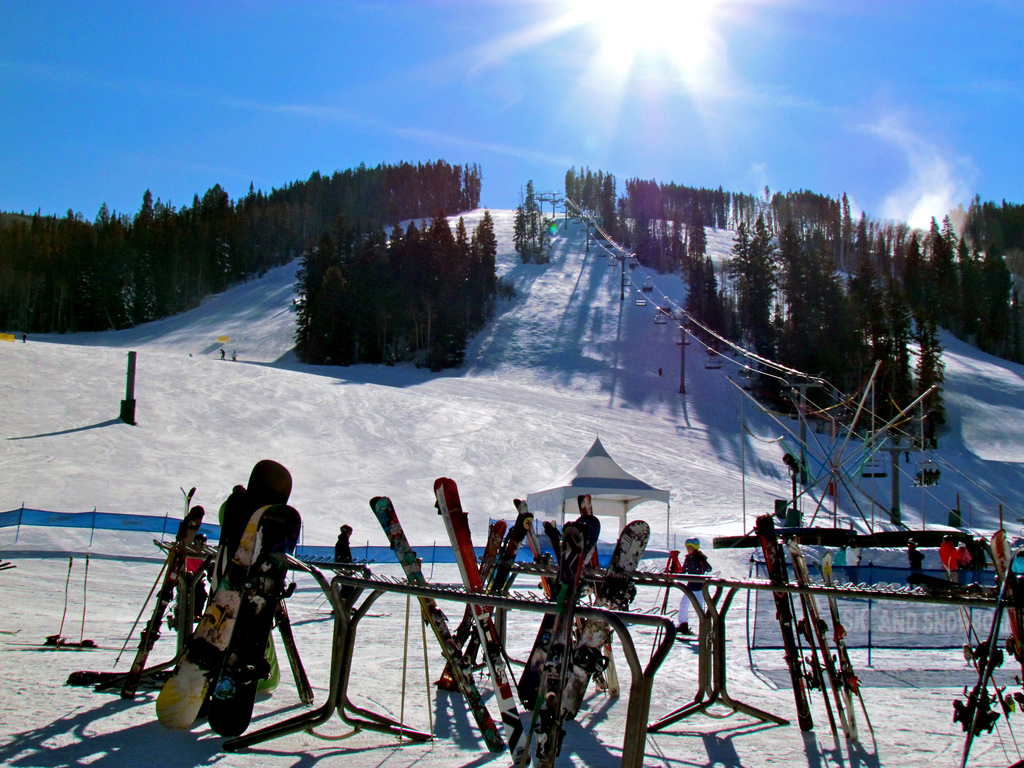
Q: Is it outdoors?
A: Yes, it is outdoors.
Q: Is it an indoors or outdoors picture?
A: It is outdoors.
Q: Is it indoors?
A: No, it is outdoors.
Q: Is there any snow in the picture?
A: Yes, there is snow.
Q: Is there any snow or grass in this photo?
A: Yes, there is snow.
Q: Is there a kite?
A: No, there are no kites.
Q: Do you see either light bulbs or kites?
A: No, there are no kites or light bulbs.